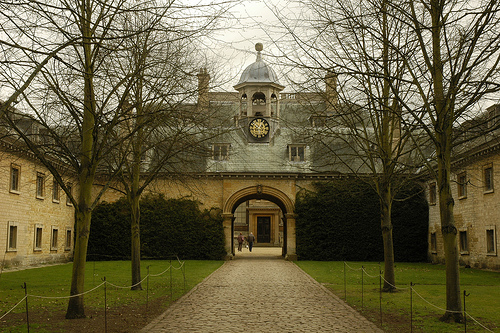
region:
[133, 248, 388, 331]
cobblestone pedestrian walkway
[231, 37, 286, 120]
blue roofed cupola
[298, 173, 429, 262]
climbing green ivy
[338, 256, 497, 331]
rope fence protecting the grass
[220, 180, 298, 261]
arched entryway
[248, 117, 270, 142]
gold clock beneath the cupola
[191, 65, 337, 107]
two red brick chimneys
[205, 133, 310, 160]
two dormer style windows in a slate roof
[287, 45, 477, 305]
tall leafless trees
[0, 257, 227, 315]
healthy bright green grass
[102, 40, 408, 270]
large overpass with a cupola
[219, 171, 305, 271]
stone archway from one courtyard to the next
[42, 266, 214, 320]
stick and wire fencing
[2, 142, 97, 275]
brick building ell with windows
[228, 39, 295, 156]
circular cupola with dome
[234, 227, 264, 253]
people walking through an archway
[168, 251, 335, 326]
brick and stone pathway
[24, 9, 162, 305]
bare trees with no leaves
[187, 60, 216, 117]
stone chimney on top of the roof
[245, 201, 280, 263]
wooden door to the brick building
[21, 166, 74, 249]
the windows are visible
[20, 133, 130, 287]
the windows are visible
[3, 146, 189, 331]
the windows are visible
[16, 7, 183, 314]
trees without leaves next to each other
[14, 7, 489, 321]
four trees without leaves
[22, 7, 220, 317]
trees without leaves during the day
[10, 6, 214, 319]
trees without leaves outside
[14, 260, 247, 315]
a roped off area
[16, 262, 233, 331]
an area that is roped off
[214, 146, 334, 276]
an archway builting over a sidewalk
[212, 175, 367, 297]
an archway built into a building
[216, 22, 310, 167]
a tower ontop of a building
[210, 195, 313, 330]
a cobble stone sidewalk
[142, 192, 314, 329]
the road is narrow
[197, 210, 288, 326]
the road is narrow